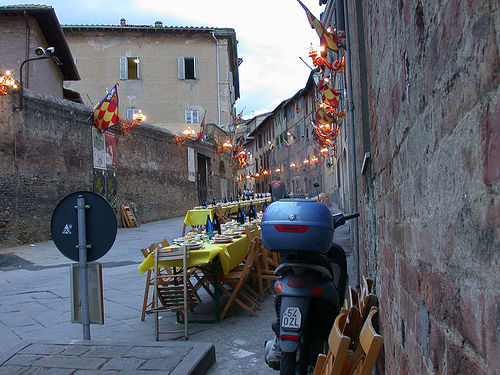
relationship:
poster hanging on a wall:
[250, 265, 302, 351] [266, 50, 474, 343]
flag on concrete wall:
[75, 70, 133, 150] [0, 84, 240, 250]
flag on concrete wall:
[195, 114, 205, 145] [0, 84, 240, 250]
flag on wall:
[313, 77, 347, 111] [238, 0, 498, 372]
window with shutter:
[179, 56, 199, 81] [188, 55, 200, 80]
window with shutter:
[179, 56, 199, 81] [176, 55, 188, 78]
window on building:
[179, 56, 199, 81] [56, 16, 246, 143]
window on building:
[118, 56, 142, 81] [62, 23, 244, 142]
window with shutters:
[118, 56, 142, 81] [117, 56, 127, 80]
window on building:
[126, 107, 141, 124] [59, 22, 235, 132]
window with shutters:
[126, 107, 141, 124] [128, 111, 137, 118]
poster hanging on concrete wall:
[90, 126, 107, 170] [0, 84, 240, 250]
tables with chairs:
[152, 254, 293, 352] [215, 240, 306, 300]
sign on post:
[42, 184, 118, 260] [75, 197, 90, 342]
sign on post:
[64, 259, 107, 322] [75, 197, 90, 342]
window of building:
[181, 108, 201, 125] [58, 22, 240, 164]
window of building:
[182, 55, 199, 81] [58, 22, 240, 164]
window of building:
[120, 51, 144, 82] [58, 22, 240, 164]